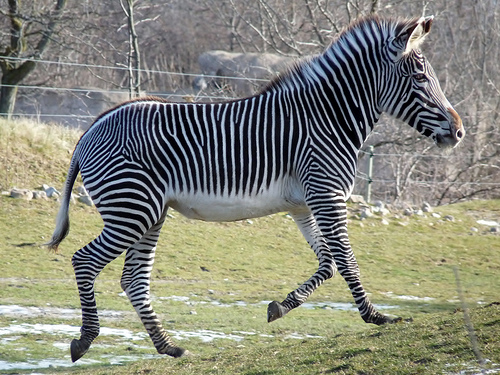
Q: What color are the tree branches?
A: Brown.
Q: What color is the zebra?
A: White and black.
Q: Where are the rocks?
A: On the ground.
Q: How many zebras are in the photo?
A: 1.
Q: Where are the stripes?
A: On the zebra.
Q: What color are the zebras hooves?
A: Black.